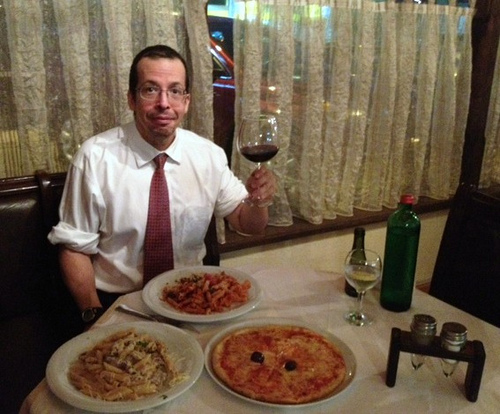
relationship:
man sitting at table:
[49, 42, 274, 327] [21, 261, 499, 413]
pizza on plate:
[210, 322, 348, 404] [205, 316, 363, 410]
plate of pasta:
[138, 263, 266, 323] [166, 275, 245, 311]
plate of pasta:
[43, 319, 206, 411] [65, 332, 187, 401]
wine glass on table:
[344, 245, 384, 331] [21, 261, 499, 413]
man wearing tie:
[49, 42, 274, 327] [138, 152, 177, 285]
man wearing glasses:
[49, 42, 274, 327] [132, 78, 185, 106]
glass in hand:
[234, 111, 281, 212] [246, 164, 277, 204]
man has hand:
[49, 42, 274, 327] [246, 164, 277, 204]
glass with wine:
[234, 111, 281, 212] [242, 142, 278, 162]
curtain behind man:
[0, 1, 475, 238] [49, 42, 274, 327]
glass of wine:
[234, 111, 281, 212] [242, 142, 278, 162]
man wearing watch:
[49, 42, 274, 327] [79, 305, 103, 326]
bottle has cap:
[378, 192, 425, 315] [396, 189, 418, 208]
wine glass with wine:
[344, 245, 384, 331] [344, 263, 384, 293]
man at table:
[49, 42, 274, 327] [21, 261, 499, 413]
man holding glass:
[49, 42, 274, 327] [234, 111, 281, 212]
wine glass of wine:
[344, 245, 384, 331] [344, 263, 384, 293]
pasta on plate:
[166, 275, 245, 311] [138, 263, 266, 323]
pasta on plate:
[65, 332, 187, 401] [43, 319, 206, 411]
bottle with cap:
[378, 192, 425, 315] [396, 189, 418, 208]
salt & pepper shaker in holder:
[405, 311, 467, 380] [377, 321, 487, 404]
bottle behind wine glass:
[341, 220, 368, 300] [344, 245, 384, 331]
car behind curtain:
[203, 16, 305, 161] [0, 1, 475, 238]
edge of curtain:
[232, 1, 478, 17] [0, 1, 475, 238]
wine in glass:
[242, 142, 278, 162] [234, 111, 281, 212]